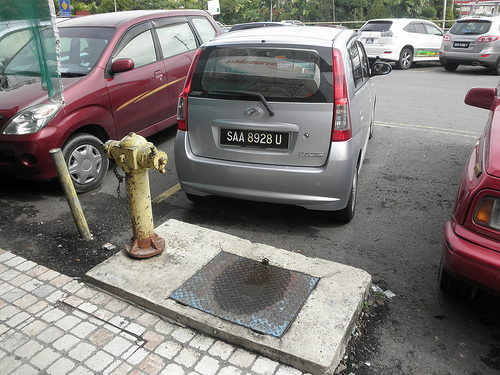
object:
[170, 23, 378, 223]
minivan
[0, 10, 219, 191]
van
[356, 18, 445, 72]
car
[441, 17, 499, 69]
car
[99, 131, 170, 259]
hydrant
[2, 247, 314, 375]
sidewalk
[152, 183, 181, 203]
line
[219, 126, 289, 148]
license plate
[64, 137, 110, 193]
front tire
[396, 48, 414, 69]
tire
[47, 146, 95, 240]
pole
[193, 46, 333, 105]
windshield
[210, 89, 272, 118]
wiper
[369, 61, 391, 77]
side mirror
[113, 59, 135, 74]
mirror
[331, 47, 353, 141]
tail lights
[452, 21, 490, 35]
rear window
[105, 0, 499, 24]
fence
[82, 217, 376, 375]
square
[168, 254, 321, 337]
cover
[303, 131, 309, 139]
keyhole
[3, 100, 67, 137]
headlight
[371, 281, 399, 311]
trash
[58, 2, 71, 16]
sign